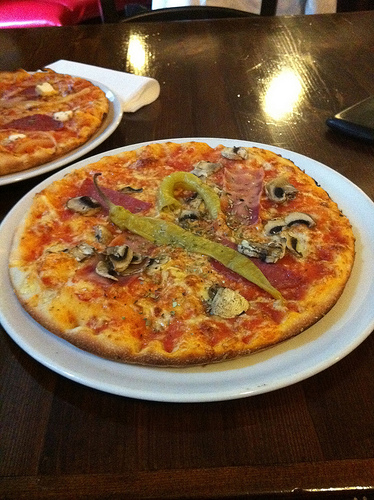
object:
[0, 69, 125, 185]
plate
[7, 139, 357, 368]
pizza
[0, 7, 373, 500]
table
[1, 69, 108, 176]
pizza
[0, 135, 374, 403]
plate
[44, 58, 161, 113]
napkin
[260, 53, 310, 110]
light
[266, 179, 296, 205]
mushroom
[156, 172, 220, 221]
pepper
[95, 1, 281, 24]
chair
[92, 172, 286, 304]
pepper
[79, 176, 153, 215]
pepperoni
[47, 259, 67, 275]
cheese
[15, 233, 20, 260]
crust